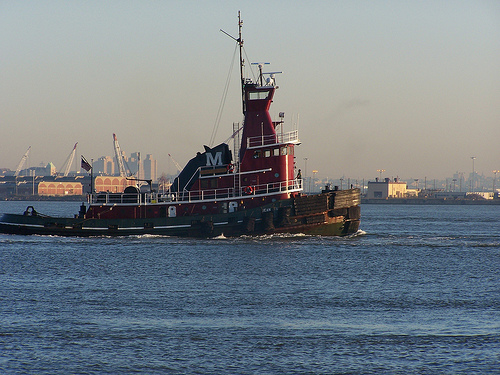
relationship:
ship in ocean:
[3, 9, 369, 225] [1, 196, 495, 374]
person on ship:
[295, 161, 303, 181] [3, 9, 369, 225]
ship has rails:
[3, 9, 369, 225] [90, 173, 304, 204]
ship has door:
[3, 9, 369, 225] [168, 207, 176, 217]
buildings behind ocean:
[82, 136, 165, 183] [1, 196, 495, 374]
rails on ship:
[90, 173, 304, 204] [3, 9, 369, 225]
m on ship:
[206, 152, 225, 166] [3, 9, 369, 225]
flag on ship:
[78, 154, 92, 177] [3, 9, 369, 225]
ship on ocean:
[3, 9, 369, 225] [1, 196, 495, 374]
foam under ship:
[131, 233, 228, 241] [3, 9, 369, 225]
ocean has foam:
[1, 196, 495, 374] [131, 233, 228, 241]